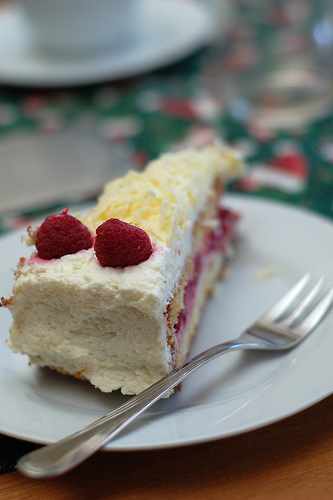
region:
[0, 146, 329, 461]
a white dish on table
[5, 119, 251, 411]
a piece of cake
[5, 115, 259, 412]
two berries on top of slice of cake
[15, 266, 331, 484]
a fork on a dish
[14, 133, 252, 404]
slice of cake cover with white frosting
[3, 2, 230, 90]
a white cup with dish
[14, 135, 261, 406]
cake has a red filling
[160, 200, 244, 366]
red filling inside a cake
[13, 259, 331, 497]
a silver fork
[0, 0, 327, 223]
a green tablecloth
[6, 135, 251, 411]
cake sitting on a white dish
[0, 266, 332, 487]
silver fork on a white dish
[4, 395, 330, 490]
plate's shadow on a wood surface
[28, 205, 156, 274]
two berries on a cake slice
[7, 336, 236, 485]
handle of a fork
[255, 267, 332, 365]
three tines of a fork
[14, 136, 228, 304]
white and yellow icing on a cake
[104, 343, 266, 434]
shadow of a fork on the plate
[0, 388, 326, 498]
wooden surface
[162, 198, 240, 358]
red cake filling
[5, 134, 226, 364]
a raspberry desert on a white plate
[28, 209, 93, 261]
a raspberry on top of a desert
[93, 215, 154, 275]
a raspberry on top of a desert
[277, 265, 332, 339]
the tines of a fork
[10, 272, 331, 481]
a fork for deserts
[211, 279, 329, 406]
a fork on a plate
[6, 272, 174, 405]
the frosted end of a desert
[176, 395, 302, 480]
a white plate on a table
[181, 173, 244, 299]
the edge of a sliced piece of desert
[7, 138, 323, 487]
a desert and fork on a white plate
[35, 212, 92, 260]
Left side raspberry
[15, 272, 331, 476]
A small silver fork.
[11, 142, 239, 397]
A piece of cake with two raspberries on top.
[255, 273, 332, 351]
Metal end of a fork with three tines.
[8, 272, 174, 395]
The white back side of a cake.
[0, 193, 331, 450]
White plate a piece of cake is on.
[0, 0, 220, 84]
A blurry white plate above the dessert.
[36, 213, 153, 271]
Two red raspberries on a cake.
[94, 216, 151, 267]
Raspberry to the right of another.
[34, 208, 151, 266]
Two red raspberries on the top of a cake.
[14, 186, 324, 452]
slice of dessert on around white plate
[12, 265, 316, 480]
silver fork on white plate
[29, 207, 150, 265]
two red raspberries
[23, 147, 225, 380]
slices of raspberry cheesecake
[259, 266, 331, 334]
light shining on tongs of fork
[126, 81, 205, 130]
red, green and white table runner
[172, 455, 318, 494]
brown wooden table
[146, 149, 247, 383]
layers of slice visible on right side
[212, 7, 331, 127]
clear glass on table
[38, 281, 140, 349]
white fluffy frosting